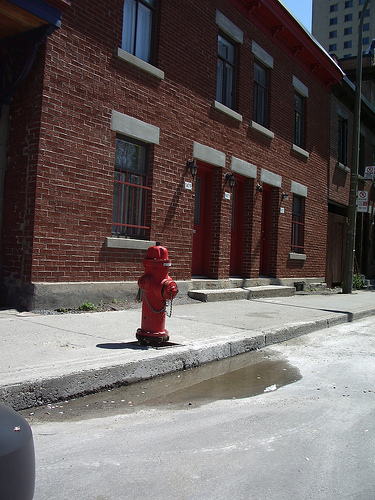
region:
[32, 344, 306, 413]
a big dirty puddle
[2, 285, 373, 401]
a long concrete sidewalk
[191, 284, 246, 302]
a concrete step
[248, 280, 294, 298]
a concrete step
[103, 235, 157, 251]
a concrete window sill of a window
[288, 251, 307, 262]
a concrete window sill of a window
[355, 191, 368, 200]
a small black and white sign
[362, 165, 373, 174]
a small black and white sign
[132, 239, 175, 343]
a red painted fire hydrant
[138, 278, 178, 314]
the metal chain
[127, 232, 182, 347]
hydrant is red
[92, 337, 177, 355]
shadow is cast on sidewalk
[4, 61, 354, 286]
building of brick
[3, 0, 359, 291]
building is red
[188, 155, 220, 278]
wall of building is red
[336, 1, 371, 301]
street pole on sidewalk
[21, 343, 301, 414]
puddle of water on street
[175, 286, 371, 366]
sidewalk of cement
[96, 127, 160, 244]
window of a house is protected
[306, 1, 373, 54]
building behind the house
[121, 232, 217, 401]
red fire hydrant by road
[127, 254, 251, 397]
water in road by fire hydrant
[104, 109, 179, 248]
red bars on window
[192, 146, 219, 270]
red door with window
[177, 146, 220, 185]
black outdoor light by doorway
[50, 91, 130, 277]
building made of brick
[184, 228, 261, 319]
concrete steps at doorways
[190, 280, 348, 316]
sidewalk along concrete steps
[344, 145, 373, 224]
signs strapped on pole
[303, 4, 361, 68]
tall building with windows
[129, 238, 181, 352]
red fire hydrant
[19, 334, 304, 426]
shallow puddle next to fire hydrant on city street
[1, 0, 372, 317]
long red brick building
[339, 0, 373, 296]
tall metal light pole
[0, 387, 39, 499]
gray car bumper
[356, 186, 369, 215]
red and white parking sign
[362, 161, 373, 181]
red and white parking sign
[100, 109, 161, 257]
window with red metal bars across it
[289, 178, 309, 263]
window with red metal bars across it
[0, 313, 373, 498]
gray concrete city street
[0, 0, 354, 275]
a red brick building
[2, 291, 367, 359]
a sidewalk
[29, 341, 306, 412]
puddle of water beside curb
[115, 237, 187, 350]
a red fire hydrant on the sidewalk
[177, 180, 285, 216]
residence address numbers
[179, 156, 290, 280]
lights on either side of doors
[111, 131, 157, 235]
red bars across window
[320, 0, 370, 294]
tall post in front of building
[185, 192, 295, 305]
cement steps in front of entrances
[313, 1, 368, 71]
tall building with square windows